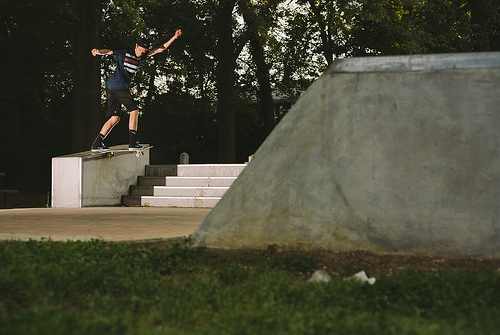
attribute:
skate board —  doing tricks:
[75, 135, 163, 174]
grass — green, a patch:
[390, 266, 439, 311]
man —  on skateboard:
[90, 25, 186, 150]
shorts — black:
[90, 84, 141, 121]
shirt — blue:
[103, 42, 152, 93]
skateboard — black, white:
[89, 130, 173, 167]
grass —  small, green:
[93, 239, 241, 333]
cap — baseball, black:
[120, 33, 152, 53]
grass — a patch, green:
[167, 267, 298, 329]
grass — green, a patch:
[1, 231, 496, 332]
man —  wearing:
[76, 22, 183, 143]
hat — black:
[130, 31, 150, 48]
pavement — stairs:
[110, 164, 181, 224]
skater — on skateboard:
[82, 26, 182, 146]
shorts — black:
[94, 90, 145, 123]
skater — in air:
[88, 28, 182, 154]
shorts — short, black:
[97, 81, 142, 118]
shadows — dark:
[89, 143, 194, 211]